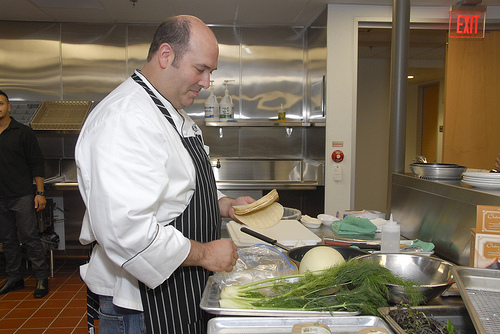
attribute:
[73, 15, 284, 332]
man — balding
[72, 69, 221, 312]
shirt — white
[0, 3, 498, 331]
kitchen — clean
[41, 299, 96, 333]
tile — red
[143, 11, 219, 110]
head — bald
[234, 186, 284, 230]
shells — tan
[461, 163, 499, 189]
plates — white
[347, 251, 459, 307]
bowl — empty, metal, round, bright, steel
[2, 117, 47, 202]
shirt — black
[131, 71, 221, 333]
apron — black, white, striped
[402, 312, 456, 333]
vegetables — gree, white, green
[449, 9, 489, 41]
sign — red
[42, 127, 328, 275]
sink — metal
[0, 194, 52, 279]
pants — black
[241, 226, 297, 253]
knife — black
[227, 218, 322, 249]
board — white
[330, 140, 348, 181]
alarm — red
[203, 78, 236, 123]
bottles — white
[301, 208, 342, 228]
dishes — white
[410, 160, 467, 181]
plates — gra